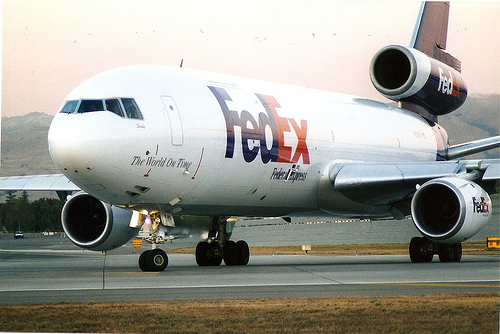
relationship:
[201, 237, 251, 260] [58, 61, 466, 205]
wheels on plane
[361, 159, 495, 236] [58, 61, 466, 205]
wing on plane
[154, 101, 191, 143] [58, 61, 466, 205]
door on plane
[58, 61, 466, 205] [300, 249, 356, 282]
plane on runway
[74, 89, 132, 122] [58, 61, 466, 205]
cockpit of plane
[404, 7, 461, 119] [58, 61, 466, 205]
tail of plane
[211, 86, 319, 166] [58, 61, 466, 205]
letters on plane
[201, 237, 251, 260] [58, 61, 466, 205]
wheels of plane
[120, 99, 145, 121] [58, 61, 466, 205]
window on plane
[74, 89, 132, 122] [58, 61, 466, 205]
cockpit on plane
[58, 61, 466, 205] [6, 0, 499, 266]
plane has jets